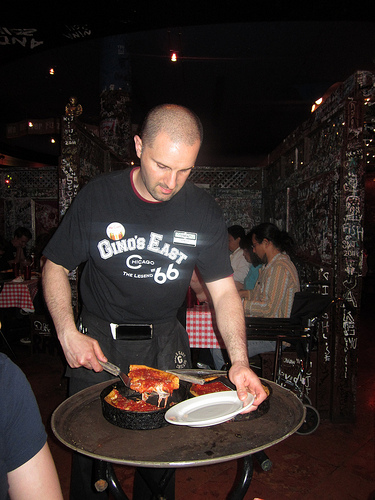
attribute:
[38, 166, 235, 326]
shirt — black